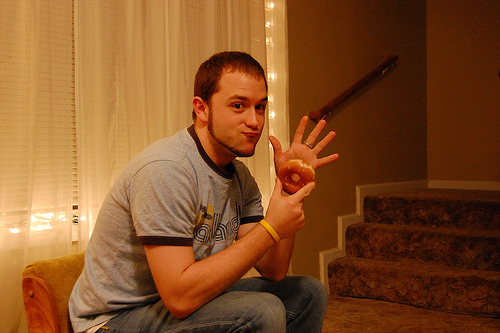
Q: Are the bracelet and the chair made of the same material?
A: No, the bracelet is made of plastic and the chair is made of wood.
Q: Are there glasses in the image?
A: No, there are no glasses.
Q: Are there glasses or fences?
A: No, there are no glasses or fences.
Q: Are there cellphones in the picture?
A: No, there are no cellphones.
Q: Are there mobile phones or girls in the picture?
A: No, there are no mobile phones or girls.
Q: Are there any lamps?
A: No, there are no lamps.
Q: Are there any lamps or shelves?
A: No, there are no lamps or shelves.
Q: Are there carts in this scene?
A: No, there are no carts.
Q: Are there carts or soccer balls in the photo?
A: No, there are no carts or soccer balls.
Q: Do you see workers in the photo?
A: No, there are no workers.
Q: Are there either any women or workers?
A: No, there are no workers or women.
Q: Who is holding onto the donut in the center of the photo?
A: The man is holding onto the donut.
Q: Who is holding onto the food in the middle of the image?
A: The man is holding onto the donut.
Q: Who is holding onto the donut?
A: The man is holding onto the donut.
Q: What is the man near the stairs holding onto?
A: The man is holding onto the doughnut.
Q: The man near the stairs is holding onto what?
A: The man is holding onto the doughnut.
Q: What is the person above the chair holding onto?
A: The man is holding onto the doughnut.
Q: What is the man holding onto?
A: The man is holding onto the doughnut.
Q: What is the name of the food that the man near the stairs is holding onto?
A: The food is a donut.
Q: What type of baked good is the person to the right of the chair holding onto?
A: The man is holding onto the doughnut.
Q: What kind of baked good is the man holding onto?
A: The man is holding onto the doughnut.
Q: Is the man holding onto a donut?
A: Yes, the man is holding onto a donut.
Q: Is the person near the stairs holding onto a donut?
A: Yes, the man is holding onto a donut.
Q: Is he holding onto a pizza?
A: No, the man is holding onto a donut.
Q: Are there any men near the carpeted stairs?
A: Yes, there is a man near the stairs.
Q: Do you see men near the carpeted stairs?
A: Yes, there is a man near the stairs.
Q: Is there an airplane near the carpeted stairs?
A: No, there is a man near the stairs.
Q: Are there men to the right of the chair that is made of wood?
A: Yes, there is a man to the right of the chair.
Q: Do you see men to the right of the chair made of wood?
A: Yes, there is a man to the right of the chair.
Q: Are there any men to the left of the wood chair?
A: No, the man is to the right of the chair.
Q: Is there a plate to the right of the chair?
A: No, there is a man to the right of the chair.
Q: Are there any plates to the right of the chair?
A: No, there is a man to the right of the chair.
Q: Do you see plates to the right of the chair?
A: No, there is a man to the right of the chair.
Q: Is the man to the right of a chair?
A: Yes, the man is to the right of a chair.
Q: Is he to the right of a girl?
A: No, the man is to the right of a chair.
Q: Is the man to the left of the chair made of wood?
A: No, the man is to the right of the chair.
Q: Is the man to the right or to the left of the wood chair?
A: The man is to the right of the chair.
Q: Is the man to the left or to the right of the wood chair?
A: The man is to the right of the chair.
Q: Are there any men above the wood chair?
A: Yes, there is a man above the chair.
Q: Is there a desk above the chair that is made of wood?
A: No, there is a man above the chair.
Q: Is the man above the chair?
A: Yes, the man is above the chair.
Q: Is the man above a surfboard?
A: No, the man is above the chair.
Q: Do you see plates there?
A: No, there are no plates.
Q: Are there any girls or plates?
A: No, there are no plates or girls.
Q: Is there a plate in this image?
A: No, there are no plates.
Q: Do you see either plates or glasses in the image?
A: No, there are no plates or glasses.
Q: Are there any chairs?
A: Yes, there is a chair.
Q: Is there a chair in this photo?
A: Yes, there is a chair.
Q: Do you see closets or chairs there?
A: Yes, there is a chair.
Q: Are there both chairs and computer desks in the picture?
A: No, there is a chair but no computer desks.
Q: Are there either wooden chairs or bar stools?
A: Yes, there is a wood chair.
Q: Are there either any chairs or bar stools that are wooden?
A: Yes, the chair is wooden.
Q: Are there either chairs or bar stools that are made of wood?
A: Yes, the chair is made of wood.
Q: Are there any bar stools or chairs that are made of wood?
A: Yes, the chair is made of wood.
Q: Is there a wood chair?
A: Yes, there is a chair that is made of wood.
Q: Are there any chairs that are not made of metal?
A: Yes, there is a chair that is made of wood.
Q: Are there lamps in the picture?
A: No, there are no lamps.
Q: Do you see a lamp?
A: No, there are no lamps.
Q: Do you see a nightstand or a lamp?
A: No, there are no lamps or nightstands.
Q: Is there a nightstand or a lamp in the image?
A: No, there are no lamps or nightstands.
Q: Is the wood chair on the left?
A: Yes, the chair is on the left of the image.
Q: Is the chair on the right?
A: No, the chair is on the left of the image.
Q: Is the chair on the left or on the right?
A: The chair is on the left of the image.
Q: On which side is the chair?
A: The chair is on the left of the image.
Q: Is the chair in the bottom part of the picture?
A: Yes, the chair is in the bottom of the image.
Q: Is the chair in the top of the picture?
A: No, the chair is in the bottom of the image.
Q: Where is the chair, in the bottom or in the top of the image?
A: The chair is in the bottom of the image.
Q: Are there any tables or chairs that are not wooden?
A: No, there is a chair but it is wooden.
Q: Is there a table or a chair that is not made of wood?
A: No, there is a chair but it is made of wood.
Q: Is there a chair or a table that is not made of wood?
A: No, there is a chair but it is made of wood.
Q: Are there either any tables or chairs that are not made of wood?
A: No, there is a chair but it is made of wood.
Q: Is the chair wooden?
A: Yes, the chair is wooden.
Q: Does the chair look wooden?
A: Yes, the chair is wooden.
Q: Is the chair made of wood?
A: Yes, the chair is made of wood.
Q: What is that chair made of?
A: The chair is made of wood.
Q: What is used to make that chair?
A: The chair is made of wood.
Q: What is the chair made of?
A: The chair is made of wood.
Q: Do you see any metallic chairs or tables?
A: No, there is a chair but it is wooden.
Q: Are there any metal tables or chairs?
A: No, there is a chair but it is wooden.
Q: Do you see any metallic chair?
A: No, there is a chair but it is wooden.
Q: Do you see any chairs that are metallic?
A: No, there is a chair but it is wooden.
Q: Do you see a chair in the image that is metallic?
A: No, there is a chair but it is wooden.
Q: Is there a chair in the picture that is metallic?
A: No, there is a chair but it is wooden.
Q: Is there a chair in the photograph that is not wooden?
A: No, there is a chair but it is wooden.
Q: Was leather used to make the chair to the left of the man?
A: No, the chair is made of wood.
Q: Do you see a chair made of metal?
A: No, there is a chair but it is made of wood.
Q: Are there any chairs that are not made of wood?
A: No, there is a chair but it is made of wood.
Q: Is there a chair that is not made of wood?
A: No, there is a chair but it is made of wood.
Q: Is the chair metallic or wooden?
A: The chair is wooden.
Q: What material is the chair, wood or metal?
A: The chair is made of wood.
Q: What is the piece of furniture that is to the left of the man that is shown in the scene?
A: The piece of furniture is a chair.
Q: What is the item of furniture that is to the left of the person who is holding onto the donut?
A: The piece of furniture is a chair.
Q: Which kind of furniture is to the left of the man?
A: The piece of furniture is a chair.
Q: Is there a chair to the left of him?
A: Yes, there is a chair to the left of the man.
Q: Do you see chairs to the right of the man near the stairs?
A: No, the chair is to the left of the man.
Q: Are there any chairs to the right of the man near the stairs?
A: No, the chair is to the left of the man.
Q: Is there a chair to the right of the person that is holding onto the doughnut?
A: No, the chair is to the left of the man.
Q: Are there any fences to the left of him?
A: No, there is a chair to the left of the man.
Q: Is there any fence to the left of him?
A: No, there is a chair to the left of the man.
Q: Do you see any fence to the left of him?
A: No, there is a chair to the left of the man.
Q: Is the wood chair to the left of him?
A: Yes, the chair is to the left of a man.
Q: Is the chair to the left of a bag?
A: No, the chair is to the left of a man.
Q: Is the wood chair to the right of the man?
A: No, the chair is to the left of the man.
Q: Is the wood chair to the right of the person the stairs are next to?
A: No, the chair is to the left of the man.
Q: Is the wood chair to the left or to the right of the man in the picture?
A: The chair is to the left of the man.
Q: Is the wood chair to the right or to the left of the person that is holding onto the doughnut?
A: The chair is to the left of the man.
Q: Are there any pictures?
A: No, there are no pictures.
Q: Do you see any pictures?
A: No, there are no pictures.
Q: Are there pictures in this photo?
A: No, there are no pictures.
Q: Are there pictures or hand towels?
A: No, there are no pictures or hand towels.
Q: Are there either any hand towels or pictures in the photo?
A: No, there are no pictures or hand towels.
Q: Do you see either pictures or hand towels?
A: No, there are no pictures or hand towels.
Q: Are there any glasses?
A: No, there are no glasses.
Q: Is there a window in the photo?
A: Yes, there is a window.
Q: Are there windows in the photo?
A: Yes, there is a window.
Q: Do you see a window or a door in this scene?
A: Yes, there is a window.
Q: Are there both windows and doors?
A: No, there is a window but no doors.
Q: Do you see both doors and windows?
A: No, there is a window but no doors.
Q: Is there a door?
A: No, there are no doors.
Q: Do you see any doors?
A: No, there are no doors.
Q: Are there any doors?
A: No, there are no doors.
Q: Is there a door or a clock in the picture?
A: No, there are no doors or clocks.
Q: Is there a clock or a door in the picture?
A: No, there are no doors or clocks.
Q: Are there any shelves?
A: No, there are no shelves.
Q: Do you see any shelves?
A: No, there are no shelves.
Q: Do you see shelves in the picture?
A: No, there are no shelves.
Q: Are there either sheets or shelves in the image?
A: No, there are no shelves or sheets.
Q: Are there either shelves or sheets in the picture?
A: No, there are no shelves or sheets.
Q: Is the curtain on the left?
A: Yes, the curtain is on the left of the image.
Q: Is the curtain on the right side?
A: No, the curtain is on the left of the image.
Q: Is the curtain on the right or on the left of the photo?
A: The curtain is on the left of the image.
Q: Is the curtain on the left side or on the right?
A: The curtain is on the left of the image.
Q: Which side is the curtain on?
A: The curtain is on the left of the image.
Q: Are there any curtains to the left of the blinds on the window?
A: Yes, there is a curtain to the left of the blinds.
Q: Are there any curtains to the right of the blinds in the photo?
A: No, the curtain is to the left of the blinds.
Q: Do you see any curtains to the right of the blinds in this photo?
A: No, the curtain is to the left of the blinds.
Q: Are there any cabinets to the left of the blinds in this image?
A: No, there is a curtain to the left of the blinds.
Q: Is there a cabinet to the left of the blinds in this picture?
A: No, there is a curtain to the left of the blinds.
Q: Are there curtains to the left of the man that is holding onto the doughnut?
A: Yes, there is a curtain to the left of the man.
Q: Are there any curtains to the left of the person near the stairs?
A: Yes, there is a curtain to the left of the man.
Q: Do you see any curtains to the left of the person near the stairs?
A: Yes, there is a curtain to the left of the man.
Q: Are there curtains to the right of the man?
A: No, the curtain is to the left of the man.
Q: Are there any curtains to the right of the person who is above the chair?
A: No, the curtain is to the left of the man.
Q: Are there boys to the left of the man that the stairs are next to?
A: No, there is a curtain to the left of the man.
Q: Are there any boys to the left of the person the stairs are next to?
A: No, there is a curtain to the left of the man.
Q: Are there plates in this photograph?
A: No, there are no plates.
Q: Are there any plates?
A: No, there are no plates.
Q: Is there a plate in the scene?
A: No, there are no plates.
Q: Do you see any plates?
A: No, there are no plates.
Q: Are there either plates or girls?
A: No, there are no plates or girls.